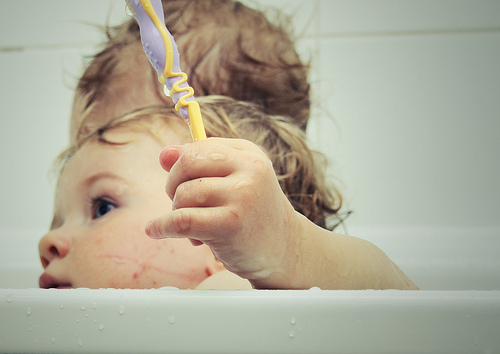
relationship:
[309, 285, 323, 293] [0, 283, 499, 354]
water drop on tub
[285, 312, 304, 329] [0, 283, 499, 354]
water drop on tub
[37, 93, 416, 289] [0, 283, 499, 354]
kid in tub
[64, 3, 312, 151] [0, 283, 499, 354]
kid in tub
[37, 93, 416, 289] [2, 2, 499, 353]
kid in bathroom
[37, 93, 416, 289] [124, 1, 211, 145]
kid holding toothbrush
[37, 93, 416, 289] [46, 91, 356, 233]
kid has hair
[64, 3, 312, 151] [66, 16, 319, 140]
kid has hair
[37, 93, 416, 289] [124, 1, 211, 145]
kid has toothbrush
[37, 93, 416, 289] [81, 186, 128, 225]
kid has eye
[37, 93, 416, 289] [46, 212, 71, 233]
kid has eye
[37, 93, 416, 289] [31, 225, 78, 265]
kid has nose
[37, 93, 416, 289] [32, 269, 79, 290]
kid has mouth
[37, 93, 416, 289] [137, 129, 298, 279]
kid has hand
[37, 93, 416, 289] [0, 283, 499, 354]
kid playing in tub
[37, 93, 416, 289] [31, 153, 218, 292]
kid has face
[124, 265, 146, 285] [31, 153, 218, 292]
mark on face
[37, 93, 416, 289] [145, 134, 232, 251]
kid has fingers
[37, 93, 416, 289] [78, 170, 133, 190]
kid has eyebrow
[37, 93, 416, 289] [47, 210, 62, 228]
kid has eyebrow